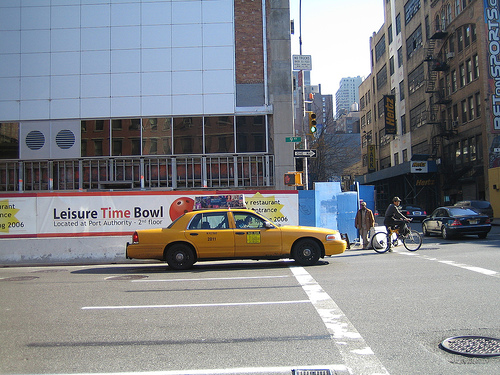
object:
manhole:
[440, 334, 500, 356]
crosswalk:
[79, 259, 391, 375]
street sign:
[285, 136, 301, 142]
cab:
[125, 207, 347, 269]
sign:
[293, 149, 318, 158]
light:
[305, 111, 317, 141]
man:
[354, 202, 374, 249]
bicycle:
[371, 217, 423, 254]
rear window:
[187, 211, 228, 229]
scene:
[0, 11, 498, 372]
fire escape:
[423, 18, 458, 156]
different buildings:
[0, 0, 500, 218]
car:
[421, 206, 491, 240]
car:
[399, 205, 426, 222]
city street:
[1, 217, 500, 374]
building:
[358, 0, 500, 224]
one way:
[295, 150, 316, 157]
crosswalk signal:
[282, 171, 304, 187]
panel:
[0, 189, 299, 265]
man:
[384, 196, 410, 252]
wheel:
[291, 238, 322, 265]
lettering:
[54, 205, 164, 220]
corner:
[346, 233, 369, 251]